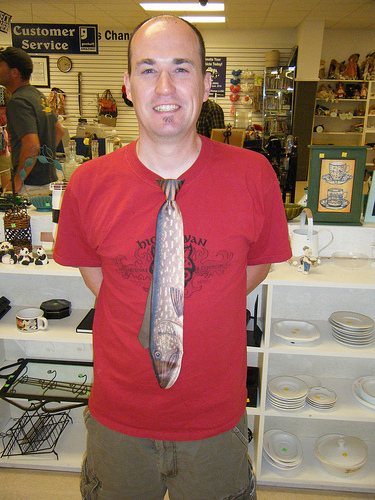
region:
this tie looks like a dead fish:
[142, 175, 195, 390]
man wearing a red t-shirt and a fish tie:
[53, 133, 296, 443]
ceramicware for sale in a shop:
[261, 302, 373, 480]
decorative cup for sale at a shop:
[12, 307, 50, 333]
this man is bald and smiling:
[122, 13, 213, 146]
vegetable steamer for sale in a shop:
[262, 47, 282, 68]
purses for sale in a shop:
[94, 86, 120, 129]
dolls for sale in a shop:
[310, 48, 373, 120]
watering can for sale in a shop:
[284, 205, 335, 263]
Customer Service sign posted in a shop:
[7, 21, 100, 56]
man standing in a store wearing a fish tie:
[49, 12, 295, 498]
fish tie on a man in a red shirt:
[139, 172, 193, 392]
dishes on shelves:
[258, 285, 374, 493]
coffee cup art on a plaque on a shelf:
[298, 139, 371, 230]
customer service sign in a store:
[9, 18, 102, 60]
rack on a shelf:
[0, 397, 80, 463]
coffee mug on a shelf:
[12, 302, 50, 336]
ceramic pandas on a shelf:
[0, 235, 53, 271]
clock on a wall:
[54, 53, 75, 77]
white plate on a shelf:
[268, 314, 323, 348]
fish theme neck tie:
[142, 178, 184, 389]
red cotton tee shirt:
[54, 139, 282, 437]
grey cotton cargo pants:
[81, 408, 256, 499]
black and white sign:
[10, 21, 96, 55]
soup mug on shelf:
[14, 308, 48, 332]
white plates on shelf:
[268, 375, 307, 412]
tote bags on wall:
[96, 89, 118, 127]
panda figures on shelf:
[1, 241, 49, 267]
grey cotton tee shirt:
[5, 87, 58, 185]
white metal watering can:
[289, 207, 334, 261]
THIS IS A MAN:
[67, 19, 297, 498]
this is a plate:
[265, 421, 301, 464]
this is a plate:
[330, 308, 373, 333]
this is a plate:
[249, 448, 305, 471]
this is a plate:
[315, 426, 368, 483]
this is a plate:
[268, 370, 306, 398]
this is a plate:
[264, 387, 310, 417]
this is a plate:
[306, 377, 351, 415]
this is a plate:
[268, 312, 321, 353]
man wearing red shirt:
[55, 18, 285, 496]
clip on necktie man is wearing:
[134, 171, 195, 394]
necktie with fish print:
[142, 182, 194, 387]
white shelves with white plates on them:
[259, 280, 372, 477]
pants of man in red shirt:
[81, 426, 253, 498]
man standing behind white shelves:
[2, 39, 66, 200]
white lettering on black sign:
[9, 23, 103, 55]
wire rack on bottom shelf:
[1, 392, 62, 470]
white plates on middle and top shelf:
[277, 298, 370, 413]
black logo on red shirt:
[118, 212, 223, 296]